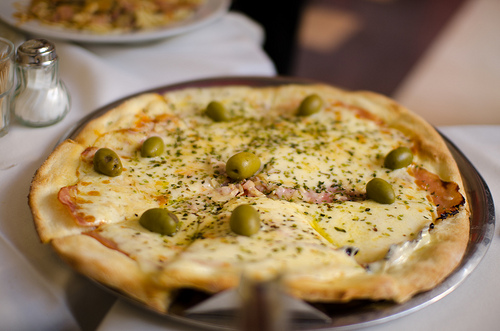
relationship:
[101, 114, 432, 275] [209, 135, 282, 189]
pizza has green olives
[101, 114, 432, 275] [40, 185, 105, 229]
pizza has ham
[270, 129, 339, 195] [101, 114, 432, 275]
cheese on pizza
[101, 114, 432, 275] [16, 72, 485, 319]
pizza on pizza pan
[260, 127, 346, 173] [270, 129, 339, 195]
green herbs on cheese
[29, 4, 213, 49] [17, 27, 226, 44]
food on plate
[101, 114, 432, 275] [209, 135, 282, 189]
pizza with green olives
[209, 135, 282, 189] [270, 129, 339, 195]
green olives on cheese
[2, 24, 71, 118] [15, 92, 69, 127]
salt shaker with salt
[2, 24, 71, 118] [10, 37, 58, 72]
salt shaker has top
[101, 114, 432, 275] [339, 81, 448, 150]
pizza has pizza crust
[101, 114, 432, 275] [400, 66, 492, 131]
pizza restaurat small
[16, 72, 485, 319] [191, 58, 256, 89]
pizza pan has edge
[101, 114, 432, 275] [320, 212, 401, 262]
pizza cheese melted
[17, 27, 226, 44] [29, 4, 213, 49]
plate of food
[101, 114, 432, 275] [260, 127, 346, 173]
pizza with green herbs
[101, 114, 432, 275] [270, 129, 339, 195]
pizza with cheese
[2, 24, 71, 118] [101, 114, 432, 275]
salt shaker close to pizza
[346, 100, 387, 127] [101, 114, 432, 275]
sauce of pizza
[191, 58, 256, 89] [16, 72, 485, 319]
edge of pizza pan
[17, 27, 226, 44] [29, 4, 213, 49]
plate with food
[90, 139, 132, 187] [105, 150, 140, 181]
green olive with hole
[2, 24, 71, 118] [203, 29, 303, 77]
salt shaker of table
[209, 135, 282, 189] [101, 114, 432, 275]
green olives of pizza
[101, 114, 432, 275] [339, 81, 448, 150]
pizza with pizza crust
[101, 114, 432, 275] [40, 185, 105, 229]
pizza with ham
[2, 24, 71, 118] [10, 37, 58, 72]
salt shaker with top